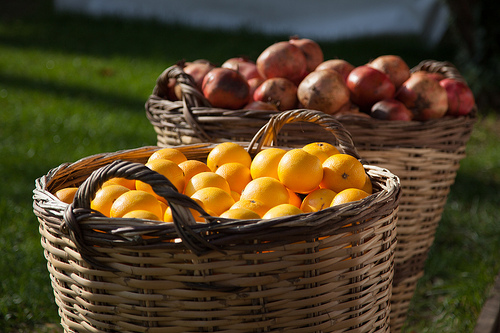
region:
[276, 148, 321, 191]
a bright yellow orange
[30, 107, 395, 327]
a brown wicker basket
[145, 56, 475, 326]
a brown wicker basket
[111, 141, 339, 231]
yellow food in basket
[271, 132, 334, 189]
round fruit in basket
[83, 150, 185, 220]
handle of the basket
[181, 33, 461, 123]
purple food in a basket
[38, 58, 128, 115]
shadow on the ground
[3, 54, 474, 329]
two baskets with food inside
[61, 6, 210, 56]
grass in the distance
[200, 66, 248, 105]
a red pomegranate fruit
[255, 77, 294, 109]
a red pomegranate fruit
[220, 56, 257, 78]
a red pomegranate fruit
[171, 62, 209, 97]
a red pomegranate fruit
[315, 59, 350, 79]
a red pomegranate fruit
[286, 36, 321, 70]
a red pomegranate fruit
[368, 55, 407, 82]
a red pomegranate fruit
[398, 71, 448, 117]
a red pomegranate fruit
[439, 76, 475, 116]
a red pomegranate fruit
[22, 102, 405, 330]
brown wicker basket with oranges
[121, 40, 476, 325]
brown wicker basket with red apples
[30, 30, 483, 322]
two wicker baskets sitting in green field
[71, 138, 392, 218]
many oranges stacked in basket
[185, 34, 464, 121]
many red apples stack in basket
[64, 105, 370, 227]
two brown wicker handles on basket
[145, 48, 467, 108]
two brown wicker handles on basket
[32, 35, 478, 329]
two brown wicker baskets with orange and red fruit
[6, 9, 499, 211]
dark shadows on green grass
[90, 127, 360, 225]
yellow lemon in the basket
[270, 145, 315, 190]
yellow lemon in the basket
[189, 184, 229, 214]
yellow lemon in the basket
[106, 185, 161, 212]
yellow lemon in the basket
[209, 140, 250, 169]
yellow lemon in the basket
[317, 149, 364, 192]
yellow lemon in the basket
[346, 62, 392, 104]
red potato in the basket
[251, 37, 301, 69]
red potato in the basket